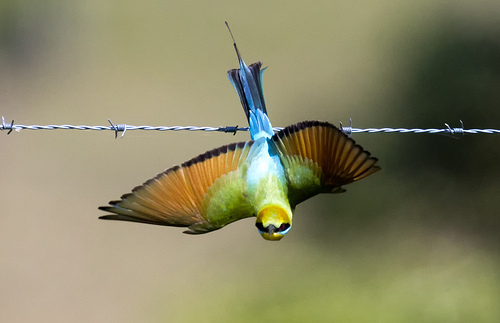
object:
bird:
[85, 26, 385, 254]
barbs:
[3, 117, 25, 135]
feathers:
[265, 186, 270, 198]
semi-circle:
[257, 206, 290, 227]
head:
[251, 213, 296, 241]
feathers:
[255, 108, 270, 134]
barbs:
[97, 118, 132, 138]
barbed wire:
[0, 122, 498, 136]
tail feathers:
[215, 15, 267, 114]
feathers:
[95, 142, 249, 236]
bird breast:
[250, 140, 279, 176]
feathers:
[260, 143, 267, 158]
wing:
[96, 150, 235, 244]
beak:
[266, 226, 277, 236]